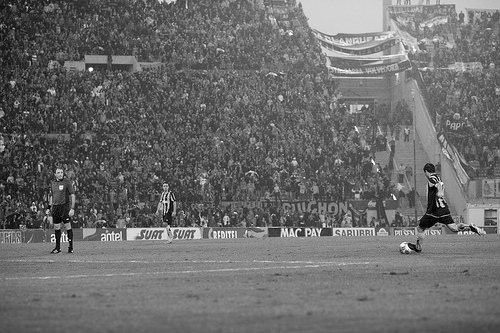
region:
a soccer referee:
[56, 173, 71, 215]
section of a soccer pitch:
[248, 255, 281, 288]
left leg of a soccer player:
[416, 227, 421, 246]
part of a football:
[401, 242, 407, 252]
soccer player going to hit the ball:
[417, 166, 444, 252]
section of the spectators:
[198, 75, 298, 159]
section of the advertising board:
[236, 231, 263, 236]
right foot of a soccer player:
[456, 223, 471, 228]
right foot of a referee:
[54, 226, 59, 248]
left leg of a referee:
[68, 225, 69, 253]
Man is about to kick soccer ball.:
[378, 217, 440, 285]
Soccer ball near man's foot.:
[348, 185, 434, 294]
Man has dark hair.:
[393, 137, 446, 214]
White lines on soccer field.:
[111, 248, 278, 328]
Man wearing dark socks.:
[38, 230, 90, 266]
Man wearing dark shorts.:
[41, 195, 93, 236]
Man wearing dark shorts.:
[140, 205, 225, 277]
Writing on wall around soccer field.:
[76, 225, 263, 250]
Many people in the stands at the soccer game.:
[114, 81, 392, 215]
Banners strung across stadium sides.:
[317, 32, 444, 107]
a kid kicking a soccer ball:
[392, 152, 488, 265]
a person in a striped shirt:
[146, 178, 184, 248]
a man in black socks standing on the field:
[41, 161, 86, 258]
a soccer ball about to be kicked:
[393, 239, 413, 256]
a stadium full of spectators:
[3, 0, 496, 239]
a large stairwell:
[340, 99, 477, 233]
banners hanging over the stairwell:
[302, 16, 423, 93]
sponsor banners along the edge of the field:
[2, 226, 492, 246]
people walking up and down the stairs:
[346, 94, 439, 221]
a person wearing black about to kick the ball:
[398, 156, 484, 268]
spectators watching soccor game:
[30, 42, 428, 224]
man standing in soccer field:
[19, 165, 101, 273]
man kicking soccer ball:
[334, 151, 472, 307]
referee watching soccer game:
[142, 179, 211, 260]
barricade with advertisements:
[11, 207, 476, 254]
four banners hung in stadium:
[311, 25, 421, 145]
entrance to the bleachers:
[59, 47, 186, 138]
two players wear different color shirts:
[42, 154, 456, 251]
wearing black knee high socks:
[49, 159, 119, 299]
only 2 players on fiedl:
[37, 162, 439, 330]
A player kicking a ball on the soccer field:
[401, 144, 464, 252]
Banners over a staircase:
[306, 24, 439, 90]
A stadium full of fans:
[194, 95, 337, 191]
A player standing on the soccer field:
[30, 161, 97, 257]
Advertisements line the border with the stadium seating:
[201, 222, 377, 240]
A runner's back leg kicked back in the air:
[407, 193, 498, 258]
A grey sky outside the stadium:
[308, 5, 379, 33]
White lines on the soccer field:
[217, 254, 365, 289]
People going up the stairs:
[392, 154, 421, 204]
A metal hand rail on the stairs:
[371, 117, 391, 146]